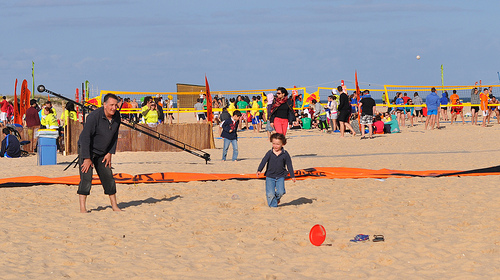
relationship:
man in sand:
[58, 83, 139, 219] [120, 220, 272, 261]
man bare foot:
[58, 83, 139, 219] [108, 204, 128, 215]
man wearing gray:
[58, 83, 139, 219] [85, 114, 115, 153]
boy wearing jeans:
[260, 132, 296, 208] [263, 177, 290, 206]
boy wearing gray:
[260, 132, 296, 208] [264, 151, 286, 170]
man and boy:
[58, 83, 139, 219] [260, 132, 296, 208]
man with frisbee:
[58, 83, 139, 219] [304, 222, 336, 259]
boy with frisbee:
[260, 132, 296, 208] [304, 222, 336, 259]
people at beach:
[156, 90, 383, 128] [340, 145, 461, 163]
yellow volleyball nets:
[383, 100, 398, 109] [381, 83, 496, 110]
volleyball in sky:
[414, 53, 424, 63] [58, 15, 434, 44]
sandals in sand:
[354, 232, 385, 245] [120, 220, 272, 261]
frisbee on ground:
[304, 222, 336, 259] [155, 222, 405, 263]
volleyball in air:
[414, 53, 424, 63] [8, 7, 498, 38]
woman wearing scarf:
[263, 85, 293, 133] [271, 93, 289, 106]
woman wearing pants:
[263, 85, 293, 133] [273, 117, 294, 132]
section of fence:
[180, 126, 199, 141] [72, 119, 207, 146]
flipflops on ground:
[351, 229, 392, 248] [155, 222, 405, 263]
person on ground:
[370, 113, 391, 134] [155, 222, 405, 263]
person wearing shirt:
[370, 113, 391, 134] [374, 120, 384, 130]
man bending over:
[58, 83, 139, 219] [96, 141, 99, 145]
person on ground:
[2, 129, 22, 159] [155, 222, 405, 263]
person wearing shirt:
[2, 129, 22, 159] [3, 133, 21, 152]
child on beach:
[225, 110, 244, 166] [340, 145, 461, 163]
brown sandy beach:
[308, 135, 311, 140] [340, 145, 461, 163]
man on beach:
[58, 83, 139, 219] [340, 145, 461, 163]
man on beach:
[337, 83, 354, 136] [340, 145, 461, 163]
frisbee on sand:
[304, 222, 336, 259] [120, 220, 272, 261]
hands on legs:
[81, 157, 113, 171] [78, 163, 125, 200]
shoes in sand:
[354, 232, 385, 245] [120, 220, 272, 261]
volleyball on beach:
[414, 53, 424, 63] [340, 145, 461, 163]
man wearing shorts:
[428, 83, 442, 131] [425, 108, 440, 117]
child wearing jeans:
[260, 132, 296, 208] [263, 177, 290, 206]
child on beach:
[260, 132, 296, 208] [340, 145, 461, 163]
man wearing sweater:
[58, 83, 139, 219] [81, 108, 126, 153]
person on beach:
[358, 87, 381, 139] [340, 145, 461, 163]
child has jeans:
[225, 110, 244, 166] [263, 177, 290, 206]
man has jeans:
[58, 83, 139, 219] [77, 156, 121, 201]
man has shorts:
[428, 83, 442, 131] [425, 108, 440, 117]